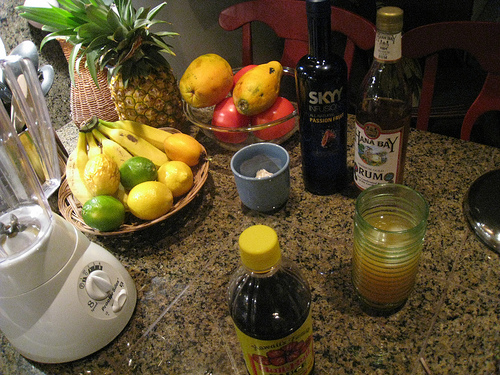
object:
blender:
[0, 56, 139, 366]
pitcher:
[0, 53, 65, 261]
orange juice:
[354, 211, 423, 303]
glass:
[350, 179, 429, 318]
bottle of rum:
[349, 5, 409, 203]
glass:
[353, 61, 414, 133]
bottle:
[305, 0, 335, 42]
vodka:
[296, 0, 351, 198]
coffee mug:
[229, 141, 292, 212]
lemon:
[126, 178, 176, 221]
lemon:
[153, 159, 193, 199]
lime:
[82, 193, 127, 233]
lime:
[115, 154, 158, 193]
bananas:
[93, 116, 172, 171]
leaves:
[83, 48, 102, 91]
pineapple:
[13, 0, 191, 135]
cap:
[375, 5, 406, 28]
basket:
[56, 126, 213, 237]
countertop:
[0, 75, 498, 373]